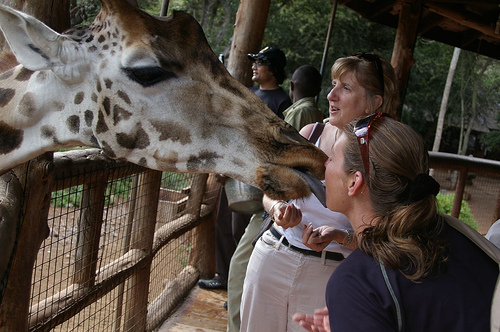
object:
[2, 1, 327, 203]
giraffe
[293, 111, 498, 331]
lady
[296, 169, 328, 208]
tongue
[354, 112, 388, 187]
sunglasses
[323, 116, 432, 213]
head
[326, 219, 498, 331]
shirt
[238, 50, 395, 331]
lady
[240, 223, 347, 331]
pants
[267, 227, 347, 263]
belt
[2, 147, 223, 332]
fence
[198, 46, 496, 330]
people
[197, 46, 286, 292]
man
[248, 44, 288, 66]
cap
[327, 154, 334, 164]
eyes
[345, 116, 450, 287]
hair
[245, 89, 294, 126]
shirt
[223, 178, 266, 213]
bucket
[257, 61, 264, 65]
glasses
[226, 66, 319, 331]
male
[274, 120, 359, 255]
tank top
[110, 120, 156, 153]
spots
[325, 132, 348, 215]
face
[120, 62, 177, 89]
eye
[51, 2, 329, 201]
head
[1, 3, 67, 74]
ear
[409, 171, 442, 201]
scrunchie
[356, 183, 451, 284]
ponytail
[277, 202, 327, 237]
feed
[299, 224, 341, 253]
hands